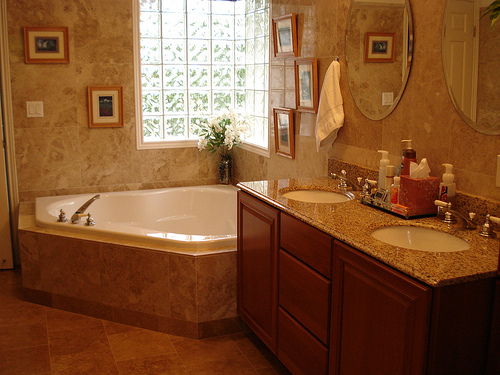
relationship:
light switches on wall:
[22, 96, 47, 120] [0, 0, 236, 202]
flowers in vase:
[190, 99, 255, 151] [212, 151, 237, 183]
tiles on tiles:
[28, 311, 178, 373] [28, 311, 178, 373]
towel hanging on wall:
[312, 58, 344, 156] [24, 23, 175, 195]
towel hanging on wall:
[312, 58, 344, 156] [231, 0, 499, 203]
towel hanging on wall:
[312, 58, 344, 156] [0, 1, 495, 199]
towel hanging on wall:
[312, 58, 344, 156] [268, 2, 495, 198]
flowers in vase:
[192, 109, 252, 155] [205, 139, 237, 191]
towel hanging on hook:
[312, 58, 344, 156] [330, 49, 342, 64]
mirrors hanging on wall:
[343, 1, 414, 120] [311, 3, 498, 242]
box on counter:
[397, 158, 439, 217] [228, 169, 496, 289]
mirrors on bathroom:
[343, 1, 499, 134] [1, 0, 499, 374]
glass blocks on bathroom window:
[149, 9, 217, 79] [132, 3, 276, 154]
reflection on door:
[438, 4, 498, 139] [441, 0, 481, 125]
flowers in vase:
[192, 109, 252, 155] [199, 103, 240, 193]